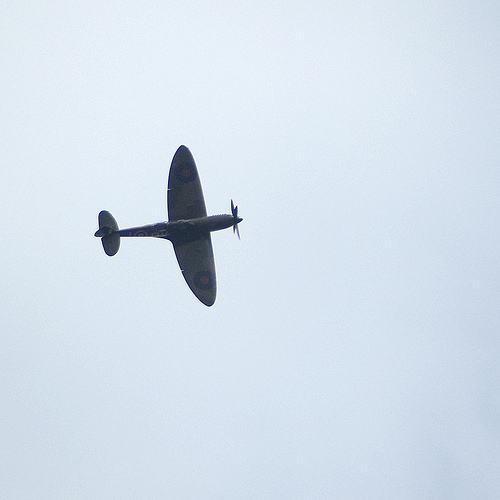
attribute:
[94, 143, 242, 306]
airplane — sideways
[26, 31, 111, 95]
clouds — white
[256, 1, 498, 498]
sky — blue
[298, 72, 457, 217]
sky — blue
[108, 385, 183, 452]
sky — blue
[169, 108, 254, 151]
wall — gray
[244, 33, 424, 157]
clouds — white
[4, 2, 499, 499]
sky — blue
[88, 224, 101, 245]
rudder — steering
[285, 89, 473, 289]
sky — blue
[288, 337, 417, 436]
cloud — white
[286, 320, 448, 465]
cloud — white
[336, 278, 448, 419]
cloud — white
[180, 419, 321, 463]
cloud — white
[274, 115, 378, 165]
cloud — white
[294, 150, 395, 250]
sky — blue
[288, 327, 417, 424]
cloud — white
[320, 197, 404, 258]
cloud — white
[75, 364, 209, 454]
cloud — white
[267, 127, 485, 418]
sky — blue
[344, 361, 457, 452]
cloud — white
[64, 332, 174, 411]
cloud — white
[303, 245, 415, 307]
cloud — white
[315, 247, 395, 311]
cloud — white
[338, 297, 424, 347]
cloud — white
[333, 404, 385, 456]
cloud — white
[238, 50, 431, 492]
sky — blue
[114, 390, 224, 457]
cloud — white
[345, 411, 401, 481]
cloud — white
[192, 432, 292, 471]
cloud — white